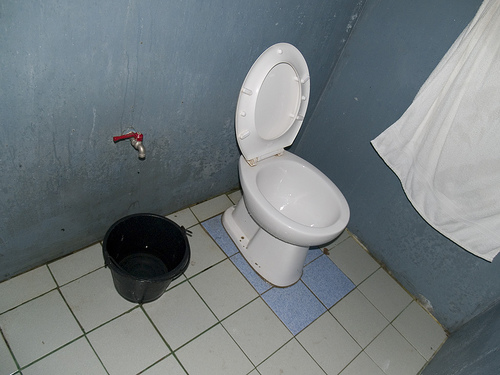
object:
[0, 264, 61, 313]
tile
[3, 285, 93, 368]
tile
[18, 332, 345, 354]
tile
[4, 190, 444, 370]
floor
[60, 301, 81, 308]
tile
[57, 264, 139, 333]
tile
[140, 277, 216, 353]
tile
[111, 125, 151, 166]
faucet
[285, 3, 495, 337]
wall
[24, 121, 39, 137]
stains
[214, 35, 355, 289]
bowl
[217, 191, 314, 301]
base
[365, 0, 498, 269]
towel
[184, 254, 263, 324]
tile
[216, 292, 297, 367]
tile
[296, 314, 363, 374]
tile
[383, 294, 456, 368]
tile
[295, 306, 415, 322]
tile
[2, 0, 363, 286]
wall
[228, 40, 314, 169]
lid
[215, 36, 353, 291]
toilet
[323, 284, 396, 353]
tiles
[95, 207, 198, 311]
bucket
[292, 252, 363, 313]
tile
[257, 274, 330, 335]
tile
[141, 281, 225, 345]
tile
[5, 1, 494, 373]
bathroom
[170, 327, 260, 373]
tile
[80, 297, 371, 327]
tile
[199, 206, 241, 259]
tile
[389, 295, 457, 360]
tile